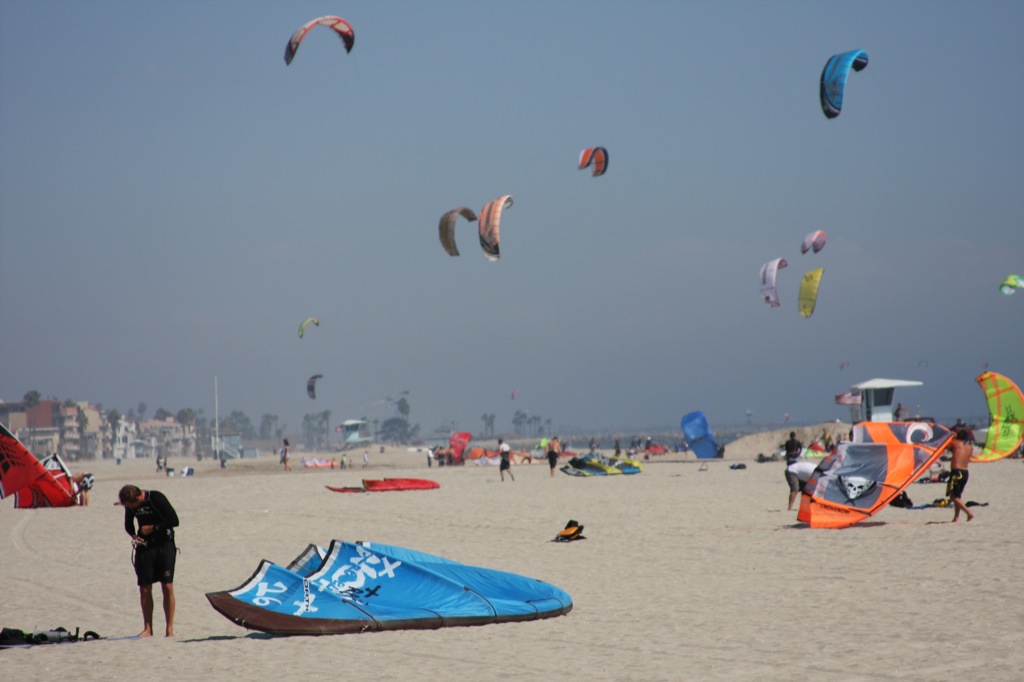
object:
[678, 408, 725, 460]
kite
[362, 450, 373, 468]
person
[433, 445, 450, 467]
person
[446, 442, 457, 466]
person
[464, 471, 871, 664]
beach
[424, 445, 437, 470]
people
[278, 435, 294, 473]
people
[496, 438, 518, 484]
people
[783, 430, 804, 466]
people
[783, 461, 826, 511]
people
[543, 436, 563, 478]
people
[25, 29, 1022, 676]
outdoors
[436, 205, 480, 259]
parasail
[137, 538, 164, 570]
black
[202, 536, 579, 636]
parachute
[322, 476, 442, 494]
parachute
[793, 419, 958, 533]
parachute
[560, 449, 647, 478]
parachute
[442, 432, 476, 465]
parachute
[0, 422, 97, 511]
parachute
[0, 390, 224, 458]
buildings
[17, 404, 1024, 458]
horizon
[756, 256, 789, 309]
parachutes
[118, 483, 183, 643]
man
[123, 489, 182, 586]
wet suit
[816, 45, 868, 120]
kite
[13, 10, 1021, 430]
sky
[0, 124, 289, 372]
clouds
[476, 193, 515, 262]
kite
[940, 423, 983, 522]
man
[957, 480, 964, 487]
black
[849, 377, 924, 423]
stand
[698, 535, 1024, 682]
sand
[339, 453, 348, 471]
person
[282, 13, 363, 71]
kite